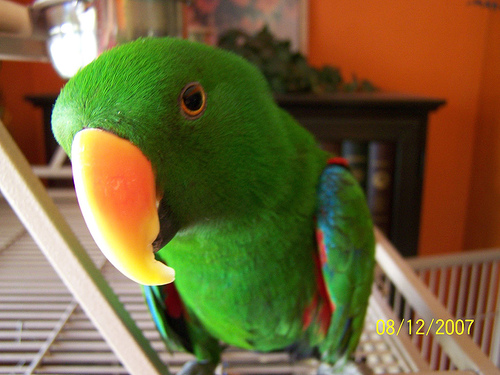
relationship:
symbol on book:
[372, 169, 391, 191] [348, 131, 419, 239]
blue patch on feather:
[319, 165, 344, 265] [315, 172, 362, 336]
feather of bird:
[315, 172, 362, 336] [43, 32, 378, 372]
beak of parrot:
[58, 123, 193, 313] [53, 38, 378, 374]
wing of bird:
[306, 148, 382, 373] [43, 32, 378, 372]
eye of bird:
[180, 83, 206, 116] [47, 53, 269, 267]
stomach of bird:
[187, 255, 303, 345] [43, 32, 378, 372]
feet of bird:
[177, 345, 230, 375] [43, 32, 378, 372]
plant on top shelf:
[221, 25, 388, 94] [19, 79, 449, 122]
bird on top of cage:
[43, 32, 378, 372] [0, 158, 497, 371]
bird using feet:
[43, 32, 378, 372] [172, 342, 273, 363]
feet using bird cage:
[172, 342, 273, 363] [0, 123, 495, 375]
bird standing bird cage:
[43, 32, 378, 372] [0, 123, 495, 375]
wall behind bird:
[313, 1, 499, 204] [50, 37, 376, 374]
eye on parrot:
[179, 81, 206, 118] [53, 38, 378, 374]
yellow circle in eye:
[176, 83, 204, 118] [179, 81, 206, 118]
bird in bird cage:
[50, 37, 376, 374] [3, 129, 496, 374]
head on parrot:
[17, 40, 288, 237] [53, 38, 378, 374]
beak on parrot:
[68, 126, 176, 287] [53, 38, 378, 374]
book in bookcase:
[343, 139, 390, 245] [282, 86, 441, 261]